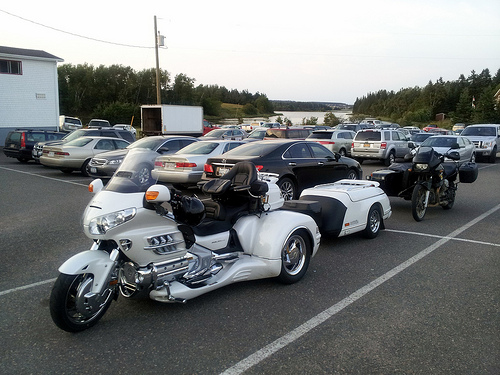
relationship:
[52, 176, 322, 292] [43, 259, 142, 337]
motorcycle has wheel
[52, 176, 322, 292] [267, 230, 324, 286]
motorcycle has rear wheel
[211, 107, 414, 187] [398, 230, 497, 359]
cars in parking lot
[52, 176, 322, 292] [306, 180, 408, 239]
motorcycle has trailer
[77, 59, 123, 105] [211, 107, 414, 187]
tree next to cars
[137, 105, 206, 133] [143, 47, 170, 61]
trailer beside telephone pole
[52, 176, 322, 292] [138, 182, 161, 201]
motorcycle has headlights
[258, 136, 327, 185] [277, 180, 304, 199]
car has wheel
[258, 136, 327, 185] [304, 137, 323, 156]
car has window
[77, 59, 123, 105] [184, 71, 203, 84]
tree has branches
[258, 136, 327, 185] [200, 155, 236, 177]
car has back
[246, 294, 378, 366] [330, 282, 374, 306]
ground has strip